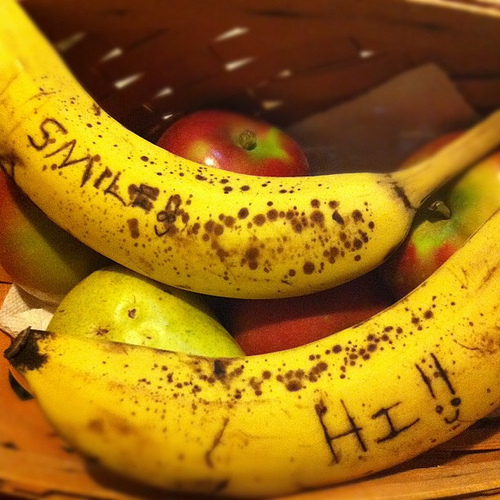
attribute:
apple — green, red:
[183, 104, 320, 180]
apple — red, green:
[414, 131, 498, 270]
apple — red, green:
[236, 307, 375, 331]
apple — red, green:
[2, 170, 109, 317]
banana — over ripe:
[1, 295, 499, 490]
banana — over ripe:
[1, 59, 496, 297]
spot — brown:
[418, 304, 435, 319]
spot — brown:
[200, 216, 232, 246]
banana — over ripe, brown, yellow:
[4, 211, 499, 498]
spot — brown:
[218, 212, 232, 227]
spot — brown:
[279, 368, 304, 391]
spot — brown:
[409, 312, 418, 324]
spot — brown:
[305, 206, 322, 226]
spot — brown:
[121, 217, 146, 240]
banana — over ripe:
[55, 57, 480, 484]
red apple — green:
[158, 108, 308, 180]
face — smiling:
[149, 210, 179, 242]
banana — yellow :
[2, 295, 494, 466]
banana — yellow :
[9, 13, 486, 270]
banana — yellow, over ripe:
[7, 4, 497, 300]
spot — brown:
[277, 365, 308, 395]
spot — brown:
[304, 199, 379, 255]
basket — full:
[4, 2, 498, 496]